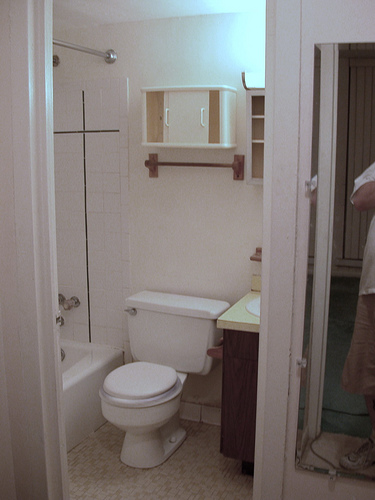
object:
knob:
[62, 296, 79, 311]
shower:
[50, 0, 127, 453]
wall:
[52, 10, 264, 423]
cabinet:
[140, 89, 233, 147]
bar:
[136, 151, 246, 183]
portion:
[240, 65, 270, 97]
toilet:
[78, 267, 252, 463]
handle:
[136, 151, 269, 184]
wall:
[25, 274, 133, 370]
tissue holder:
[205, 334, 223, 358]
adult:
[341, 152, 373, 470]